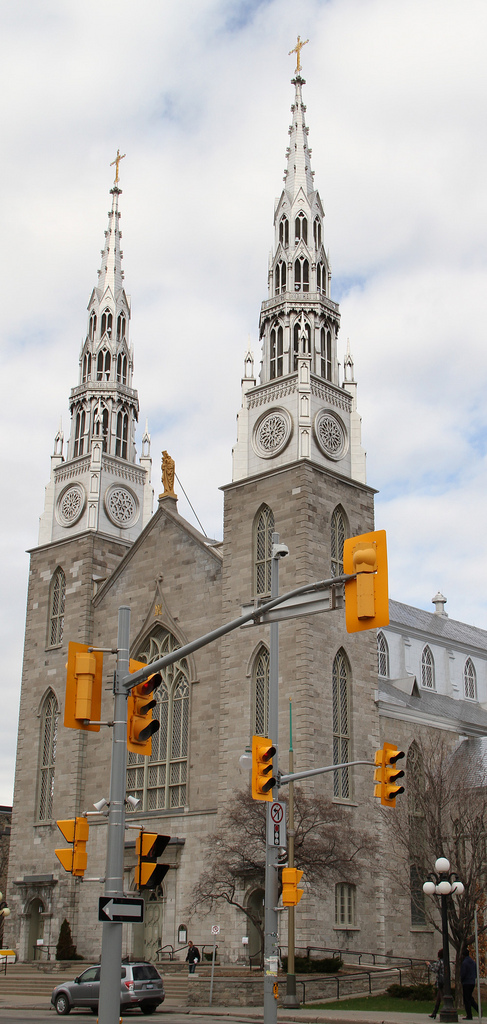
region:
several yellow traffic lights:
[32, 533, 419, 938]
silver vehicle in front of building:
[39, 958, 179, 1005]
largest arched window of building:
[100, 576, 212, 821]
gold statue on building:
[155, 441, 175, 511]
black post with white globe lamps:
[410, 835, 470, 1019]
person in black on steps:
[173, 928, 197, 988]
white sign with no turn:
[269, 788, 292, 867]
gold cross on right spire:
[269, 26, 316, 74]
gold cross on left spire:
[85, 147, 144, 208]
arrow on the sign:
[102, 898, 138, 917]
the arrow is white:
[105, 902, 143, 919]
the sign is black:
[94, 889, 153, 924]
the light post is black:
[438, 872, 450, 966]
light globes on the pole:
[421, 857, 472, 902]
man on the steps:
[182, 933, 210, 987]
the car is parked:
[56, 964, 176, 1020]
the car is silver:
[53, 960, 160, 1003]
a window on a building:
[271, 212, 289, 243]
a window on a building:
[335, 882, 360, 933]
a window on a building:
[119, 786, 146, 813]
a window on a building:
[169, 789, 185, 811]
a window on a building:
[164, 755, 195, 783]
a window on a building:
[240, 633, 265, 749]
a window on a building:
[32, 690, 62, 826]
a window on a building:
[125, 630, 189, 697]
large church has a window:
[331, 880, 358, 922]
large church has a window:
[331, 648, 353, 796]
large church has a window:
[462, 657, 476, 698]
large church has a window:
[248, 639, 266, 742]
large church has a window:
[34, 688, 61, 821]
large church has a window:
[335, 880, 355, 923]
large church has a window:
[404, 739, 428, 924]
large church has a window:
[450, 820, 463, 879]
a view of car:
[26, 935, 147, 1017]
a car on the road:
[66, 956, 197, 1019]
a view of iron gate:
[162, 934, 277, 998]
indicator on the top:
[85, 869, 187, 923]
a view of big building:
[68, 522, 386, 860]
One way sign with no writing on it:
[83, 863, 165, 936]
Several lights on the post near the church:
[403, 822, 476, 940]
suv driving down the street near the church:
[47, 930, 181, 1012]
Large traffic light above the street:
[321, 500, 394, 653]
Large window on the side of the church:
[312, 622, 405, 833]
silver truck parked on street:
[45, 962, 168, 1014]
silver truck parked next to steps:
[49, 948, 170, 1013]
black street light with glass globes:
[421, 852, 469, 1014]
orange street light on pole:
[249, 729, 278, 806]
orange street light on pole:
[360, 741, 405, 808]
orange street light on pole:
[123, 820, 175, 900]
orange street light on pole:
[47, 809, 115, 886]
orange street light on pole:
[62, 637, 132, 736]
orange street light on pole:
[328, 525, 393, 637]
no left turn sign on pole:
[262, 797, 290, 863]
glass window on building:
[374, 631, 390, 679]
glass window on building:
[332, 882, 356, 925]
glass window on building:
[243, 644, 268, 790]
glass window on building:
[330, 646, 351, 806]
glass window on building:
[421, 642, 436, 687]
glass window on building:
[462, 657, 479, 703]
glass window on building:
[36, 691, 56, 821]